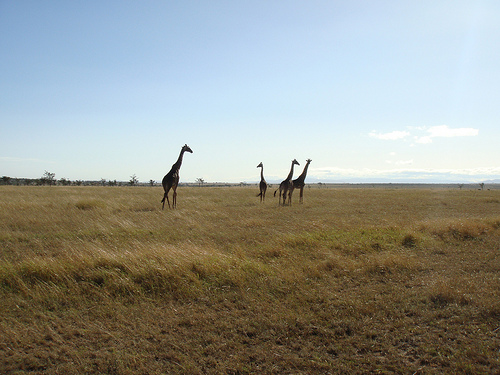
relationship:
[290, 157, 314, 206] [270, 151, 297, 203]
giraffe close to giraffe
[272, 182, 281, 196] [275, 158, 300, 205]
tail of a giraffe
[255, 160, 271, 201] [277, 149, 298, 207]
giraffe looking away from giraffe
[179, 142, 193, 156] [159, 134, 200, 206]
head of giraffe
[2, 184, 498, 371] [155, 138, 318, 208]
grass under giraffes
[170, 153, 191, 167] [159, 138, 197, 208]
neck of giraffe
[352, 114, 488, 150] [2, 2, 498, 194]
clouds in sky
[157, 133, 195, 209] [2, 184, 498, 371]
giraffe on grass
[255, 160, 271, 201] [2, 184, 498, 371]
giraffe on grass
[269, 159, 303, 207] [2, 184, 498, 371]
giraffe on grass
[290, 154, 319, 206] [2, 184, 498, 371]
giraffe on grass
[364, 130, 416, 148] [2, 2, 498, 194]
clouds in sky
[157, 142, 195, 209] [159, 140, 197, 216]
giraffe on plain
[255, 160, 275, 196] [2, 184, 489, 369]
giraffe on plain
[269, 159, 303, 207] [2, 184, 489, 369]
giraffe on plain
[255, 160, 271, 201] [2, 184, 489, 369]
giraffe on plain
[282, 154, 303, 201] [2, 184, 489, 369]
giraffe on plain